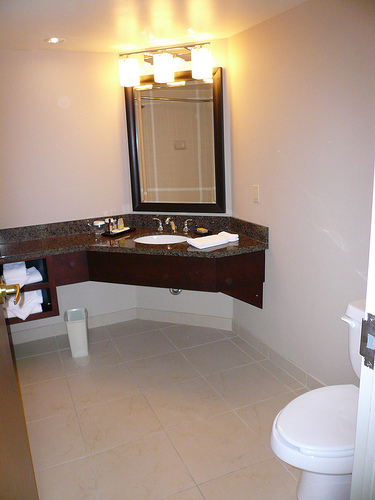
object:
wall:
[231, 1, 375, 387]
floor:
[11, 318, 327, 498]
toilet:
[268, 300, 373, 498]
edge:
[269, 392, 305, 500]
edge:
[227, 2, 284, 37]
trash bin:
[66, 307, 90, 359]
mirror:
[133, 68, 219, 203]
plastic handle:
[338, 311, 356, 326]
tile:
[126, 349, 238, 424]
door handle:
[0, 279, 22, 307]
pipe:
[168, 287, 183, 297]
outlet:
[252, 181, 259, 208]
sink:
[133, 212, 193, 247]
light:
[118, 45, 215, 89]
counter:
[0, 212, 270, 346]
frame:
[122, 60, 231, 214]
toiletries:
[93, 218, 130, 237]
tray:
[111, 227, 134, 236]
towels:
[186, 229, 239, 250]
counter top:
[0, 227, 270, 263]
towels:
[1, 259, 44, 321]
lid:
[274, 385, 359, 458]